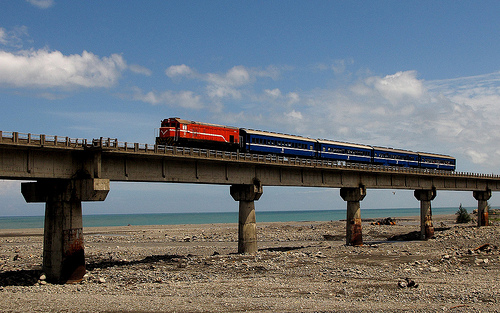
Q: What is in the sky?
A: Clouds.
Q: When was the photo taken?
A: Daytime.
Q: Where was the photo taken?
A: By beach.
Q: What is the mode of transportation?
A: Train.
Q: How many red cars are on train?
A: 1.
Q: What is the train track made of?
A: Cement.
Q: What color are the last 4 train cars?
A: Blue.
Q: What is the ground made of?
A: Sand.